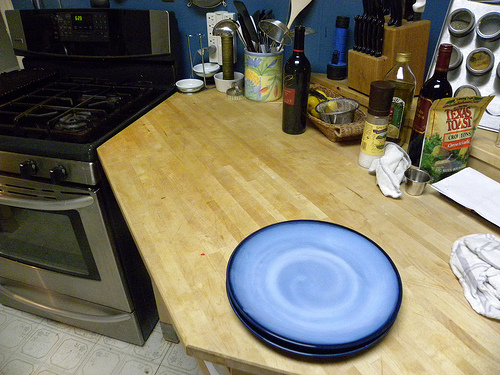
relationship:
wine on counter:
[278, 24, 310, 136] [96, 83, 498, 373]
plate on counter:
[225, 221, 401, 348] [96, 83, 498, 373]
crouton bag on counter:
[416, 94, 495, 182] [96, 83, 498, 373]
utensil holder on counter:
[240, 44, 283, 103] [96, 83, 498, 373]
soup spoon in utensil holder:
[211, 21, 250, 53] [240, 44, 283, 103]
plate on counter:
[223, 283, 391, 360] [96, 83, 498, 373]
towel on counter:
[367, 140, 410, 198] [96, 83, 498, 373]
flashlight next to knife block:
[325, 13, 350, 80] [347, 14, 430, 99]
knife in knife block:
[372, 14, 385, 59] [347, 14, 430, 99]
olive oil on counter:
[381, 51, 417, 143] [96, 83, 498, 373]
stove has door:
[1, 10, 177, 349] [3, 172, 136, 316]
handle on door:
[0, 191, 95, 213] [3, 172, 136, 316]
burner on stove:
[19, 87, 121, 131] [1, 10, 177, 349]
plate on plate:
[225, 221, 401, 348] [223, 283, 391, 360]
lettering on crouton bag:
[446, 104, 476, 131] [416, 94, 495, 182]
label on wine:
[284, 86, 297, 107] [278, 24, 310, 136]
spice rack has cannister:
[422, 1, 499, 128] [466, 48, 494, 77]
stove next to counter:
[1, 10, 177, 349] [96, 83, 498, 373]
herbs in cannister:
[470, 52, 491, 70] [466, 48, 494, 77]